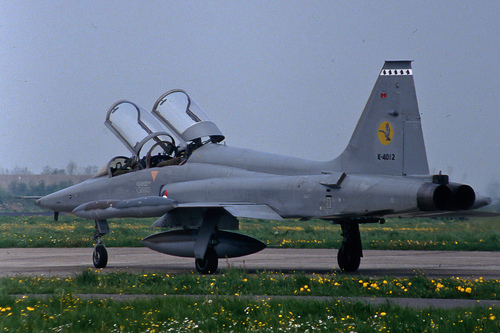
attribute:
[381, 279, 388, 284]
flower — yellow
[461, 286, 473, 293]
flower — yellow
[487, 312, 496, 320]
flower — yellow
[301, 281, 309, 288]
flower — yellow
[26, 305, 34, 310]
flower — yellow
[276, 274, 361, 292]
flowers — yellow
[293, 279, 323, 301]
flowers — yellow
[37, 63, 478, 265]
plane — light gray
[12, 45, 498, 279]
fighter jet — gray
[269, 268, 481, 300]
flowers — yellow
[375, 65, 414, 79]
design — white, black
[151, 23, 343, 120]
sky — cloudy, grey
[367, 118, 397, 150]
design — yellow